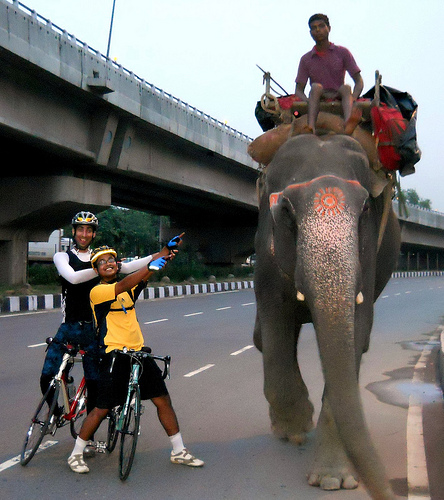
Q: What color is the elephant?
A: Gray.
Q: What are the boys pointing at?
A: Elephant.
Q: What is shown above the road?
A: Overpass.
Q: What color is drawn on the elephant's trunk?
A: Orange.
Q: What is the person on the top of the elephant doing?
A: Sitting.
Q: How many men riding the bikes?
A: 2.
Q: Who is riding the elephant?
A: A man.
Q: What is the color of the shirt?
A: Yellow.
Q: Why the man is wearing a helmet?
A: For safety.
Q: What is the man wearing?
A: Shorts.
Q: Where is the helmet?
A: On man's head.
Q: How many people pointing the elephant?
A: 2.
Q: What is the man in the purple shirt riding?
A: Elephant.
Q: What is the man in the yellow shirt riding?
A: Bicycle.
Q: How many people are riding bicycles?
A: 2.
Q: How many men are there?
A: 3.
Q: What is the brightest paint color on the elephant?
A: Orange.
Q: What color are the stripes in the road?
A: White.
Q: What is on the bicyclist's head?
A: Helmet.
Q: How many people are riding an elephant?
A: One.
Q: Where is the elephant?
A: On a freeway.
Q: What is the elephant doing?
A: Carrying a boy and his luggage.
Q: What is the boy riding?
A: An elephant.